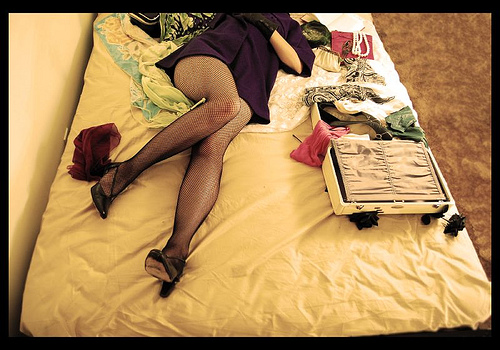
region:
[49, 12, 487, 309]
A woman lying on her bed after unpacking her luggage.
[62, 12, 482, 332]
A woman lying on her bed after unpacking her luggage.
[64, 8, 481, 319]
A woman lying on her bad after unpacking her luggage.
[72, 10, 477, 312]
A woman lying on her bad after unpacking her luggage.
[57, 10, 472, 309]
A woman lying on her bad after unpacking her luggage.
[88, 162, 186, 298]
A pair of black shoes with high heels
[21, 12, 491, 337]
A person laying on a bed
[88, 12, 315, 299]
A woman wearing a purple coat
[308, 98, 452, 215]
A white valise wide opened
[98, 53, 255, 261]
A pair of fishnets being worn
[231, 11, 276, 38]
A black leather glove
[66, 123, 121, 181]
A purple translucent scarf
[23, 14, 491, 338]
A bed covered in white sheets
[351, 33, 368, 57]
White pearls necklaces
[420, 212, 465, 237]
A black rose on the bed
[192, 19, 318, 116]
the dress is purple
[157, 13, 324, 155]
the dress is purple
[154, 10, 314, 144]
the dress is purple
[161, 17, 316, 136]
the dress is purple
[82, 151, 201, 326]
the shoes are black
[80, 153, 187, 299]
the shoes are black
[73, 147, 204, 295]
the shoes are black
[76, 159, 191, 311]
the shoes are black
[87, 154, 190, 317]
the shoes are black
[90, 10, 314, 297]
A woman is lying on the bed.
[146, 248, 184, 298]
The woman wears black heels.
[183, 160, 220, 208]
The woman wears black pantyhose.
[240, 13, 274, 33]
The woman wears black gloves.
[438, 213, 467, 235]
A black flower is on the bed.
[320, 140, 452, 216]
An open suitcase is on the bed.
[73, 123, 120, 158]
A red object is on the bed.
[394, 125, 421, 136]
A green item is in the suitcase.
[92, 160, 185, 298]
a couple of black shoes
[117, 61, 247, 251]
she is wearing black net socks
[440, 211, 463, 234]
an unrecognizable black object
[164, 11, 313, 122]
a purple short skirt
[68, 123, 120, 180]
this is a red cloth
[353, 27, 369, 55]
this is a white collar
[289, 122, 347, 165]
this is a pink cloth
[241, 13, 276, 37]
she wears black gloves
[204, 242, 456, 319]
a white bed sheet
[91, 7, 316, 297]
a sexy girl on the bed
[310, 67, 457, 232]
white suitcase next to woman on bed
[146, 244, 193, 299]
foot of woman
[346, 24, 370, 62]
pearls next to woman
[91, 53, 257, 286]
legs of woman on bed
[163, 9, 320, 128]
purple outfit woman is wearing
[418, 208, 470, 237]
black silk rose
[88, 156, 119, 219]
black leather high heeled shoe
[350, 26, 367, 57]
strand of white pearls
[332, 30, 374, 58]
red leather pouch with sipper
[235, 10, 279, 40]
black leather gloves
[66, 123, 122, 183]
a wine colored silk scarf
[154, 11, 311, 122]
short plum colored dress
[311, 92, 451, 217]
a small white suitcase open on the bed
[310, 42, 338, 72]
creamy leather makeup bag with snap clip closure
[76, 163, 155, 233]
shoe on the feet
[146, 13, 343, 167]
a person wearing a dress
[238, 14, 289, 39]
a person wearing a glove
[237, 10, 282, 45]
a person wearing a black glove